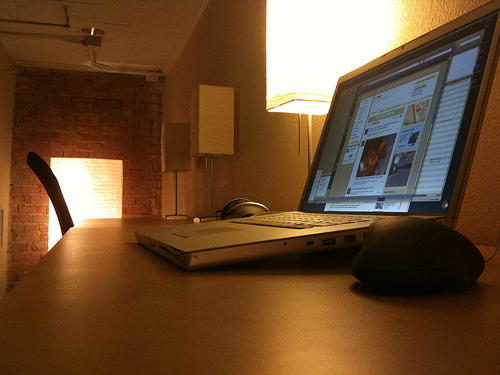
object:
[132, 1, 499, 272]
laptop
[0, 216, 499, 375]
table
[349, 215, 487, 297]
mouse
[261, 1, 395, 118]
light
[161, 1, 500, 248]
wall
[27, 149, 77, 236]
chair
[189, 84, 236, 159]
light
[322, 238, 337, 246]
usb drive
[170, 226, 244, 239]
mousepad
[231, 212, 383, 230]
keyboard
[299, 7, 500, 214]
monitor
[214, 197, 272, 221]
headphones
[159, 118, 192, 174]
shade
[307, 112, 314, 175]
pole base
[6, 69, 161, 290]
wall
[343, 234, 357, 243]
usb port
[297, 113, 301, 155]
pull chain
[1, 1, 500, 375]
room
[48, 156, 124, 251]
window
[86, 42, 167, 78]
pole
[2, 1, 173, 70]
ceiling